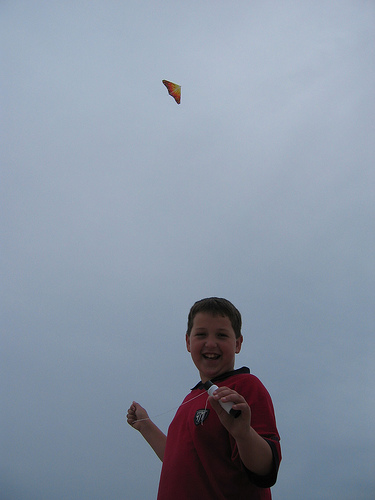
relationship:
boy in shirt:
[127, 298, 282, 500] [155, 367, 283, 499]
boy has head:
[127, 298, 282, 500] [186, 296, 244, 379]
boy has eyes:
[127, 298, 282, 500] [191, 328, 232, 339]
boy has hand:
[127, 298, 282, 500] [209, 387, 275, 480]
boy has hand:
[127, 298, 282, 500] [125, 401, 168, 462]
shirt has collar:
[155, 367, 283, 499] [190, 367, 251, 390]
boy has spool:
[127, 298, 282, 500] [203, 378, 240, 419]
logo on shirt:
[193, 408, 210, 427] [155, 367, 283, 499]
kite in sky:
[163, 78, 185, 106] [1, 6, 372, 492]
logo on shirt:
[193, 405, 210, 431] [155, 367, 283, 499]